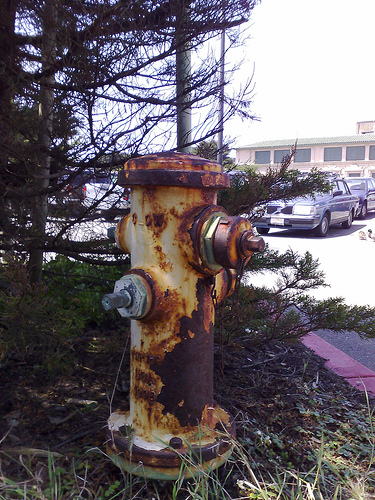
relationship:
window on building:
[253, 150, 309, 165] [235, 140, 373, 184]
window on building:
[322, 145, 345, 161] [235, 140, 373, 184]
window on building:
[345, 144, 365, 162] [235, 140, 373, 184]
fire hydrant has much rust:
[101, 146, 270, 493] [169, 300, 210, 345]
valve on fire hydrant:
[202, 207, 265, 274] [101, 146, 270, 493]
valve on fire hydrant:
[100, 270, 150, 319] [101, 146, 270, 493]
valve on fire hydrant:
[102, 213, 133, 252] [101, 146, 270, 493]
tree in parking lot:
[2, 3, 267, 380] [37, 175, 373, 307]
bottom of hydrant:
[98, 404, 241, 472] [92, 138, 259, 468]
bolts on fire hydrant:
[120, 424, 229, 449] [101, 146, 270, 493]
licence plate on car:
[269, 215, 286, 227] [249, 174, 359, 236]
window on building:
[322, 145, 345, 161] [229, 117, 373, 182]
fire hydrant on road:
[101, 146, 270, 493] [39, 212, 374, 308]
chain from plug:
[210, 276, 240, 379] [205, 215, 267, 271]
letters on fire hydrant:
[130, 347, 165, 414] [101, 146, 270, 493]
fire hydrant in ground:
[101, 146, 270, 493] [4, 285, 360, 497]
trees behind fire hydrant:
[4, 1, 226, 178] [101, 146, 270, 493]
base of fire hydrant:
[105, 398, 242, 477] [101, 146, 270, 493]